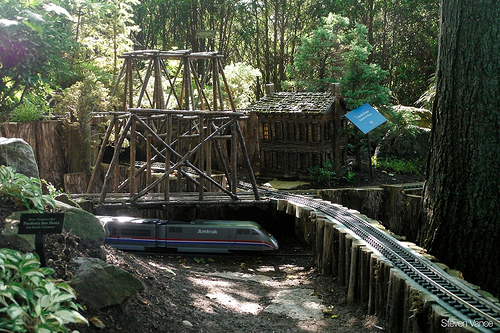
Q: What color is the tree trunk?
A: Brown.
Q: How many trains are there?
A: 1.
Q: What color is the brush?
A: Green.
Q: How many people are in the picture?
A: None.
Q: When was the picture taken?
A: In the daytime.